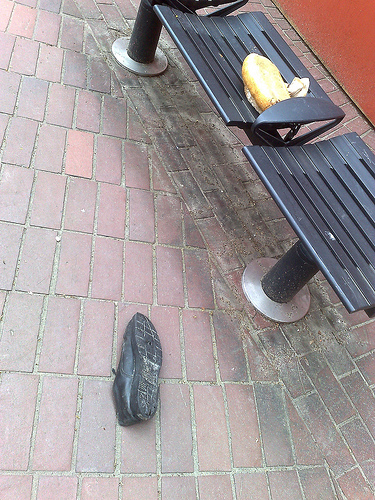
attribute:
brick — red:
[73, 391, 157, 476]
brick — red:
[283, 372, 344, 452]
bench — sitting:
[241, 130, 373, 323]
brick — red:
[77, 140, 186, 255]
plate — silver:
[218, 254, 333, 334]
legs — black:
[258, 263, 311, 306]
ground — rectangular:
[4, 226, 106, 343]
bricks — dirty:
[162, 109, 228, 207]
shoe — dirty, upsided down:
[109, 313, 160, 427]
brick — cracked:
[97, 1, 126, 61]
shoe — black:
[113, 310, 160, 421]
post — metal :
[251, 230, 322, 312]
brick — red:
[189, 379, 234, 474]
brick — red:
[30, 375, 81, 472]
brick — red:
[75, 297, 119, 376]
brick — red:
[86, 235, 124, 299]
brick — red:
[154, 245, 183, 309]